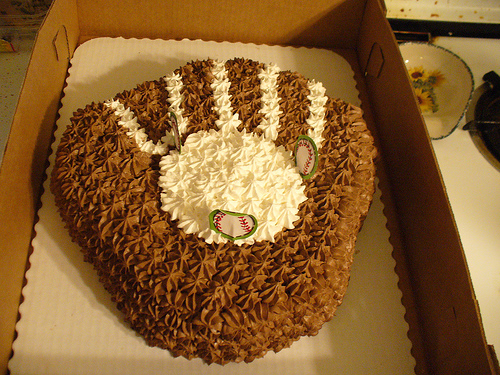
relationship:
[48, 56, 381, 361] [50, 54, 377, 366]
frosting on cake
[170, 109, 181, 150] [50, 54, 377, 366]
decoration on cake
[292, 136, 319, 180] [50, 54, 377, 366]
baseball decoration on cake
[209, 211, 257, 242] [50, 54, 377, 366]
decoration on cake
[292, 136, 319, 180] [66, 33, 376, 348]
baseball decoration with border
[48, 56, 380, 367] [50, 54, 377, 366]
frosting on cake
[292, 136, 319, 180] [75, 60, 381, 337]
baseball decoration in frosting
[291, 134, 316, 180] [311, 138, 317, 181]
baseball decoration with border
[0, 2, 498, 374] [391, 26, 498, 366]
box on counter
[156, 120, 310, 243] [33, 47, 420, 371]
circle in middle of cake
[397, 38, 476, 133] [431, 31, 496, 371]
tan bowl on stove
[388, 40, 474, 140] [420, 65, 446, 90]
saucer with daisy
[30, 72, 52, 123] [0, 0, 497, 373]
part of delivery box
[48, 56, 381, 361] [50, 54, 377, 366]
frosting of cake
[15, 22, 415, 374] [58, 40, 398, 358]
paper under cake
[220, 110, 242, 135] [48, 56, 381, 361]
star of frosting